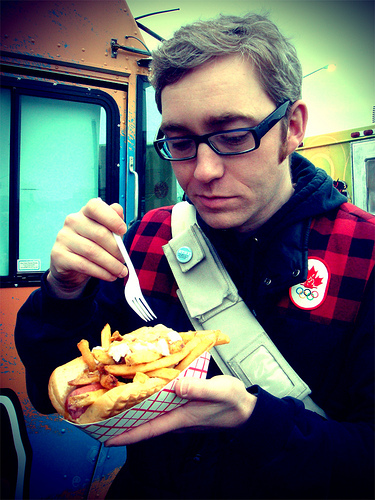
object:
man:
[14, 9, 375, 500]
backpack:
[161, 199, 327, 426]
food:
[99, 343, 166, 405]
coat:
[12, 151, 375, 500]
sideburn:
[276, 119, 287, 163]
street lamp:
[299, 61, 338, 77]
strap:
[162, 201, 325, 415]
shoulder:
[121, 202, 202, 283]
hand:
[103, 374, 256, 451]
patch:
[288, 253, 330, 310]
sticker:
[16, 257, 43, 269]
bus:
[0, 0, 154, 499]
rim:
[151, 126, 261, 163]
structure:
[1, 0, 140, 195]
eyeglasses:
[152, 100, 292, 165]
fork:
[113, 229, 156, 323]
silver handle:
[112, 227, 134, 279]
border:
[320, 259, 331, 304]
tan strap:
[163, 199, 325, 418]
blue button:
[176, 245, 191, 264]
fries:
[75, 339, 94, 374]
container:
[58, 336, 210, 444]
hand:
[47, 195, 129, 288]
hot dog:
[64, 383, 105, 418]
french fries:
[103, 348, 191, 377]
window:
[2, 70, 126, 292]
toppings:
[75, 324, 179, 383]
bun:
[47, 322, 228, 424]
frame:
[11, 71, 124, 296]